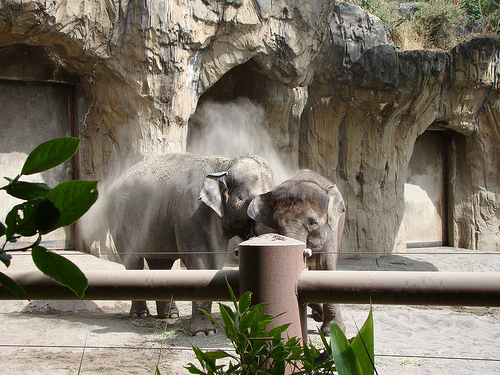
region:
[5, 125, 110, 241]
green leaves with some holes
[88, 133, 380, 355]
elephants behind a railing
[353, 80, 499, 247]
door in a stone wall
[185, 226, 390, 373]
green foliage by a post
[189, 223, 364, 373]
post and green leaves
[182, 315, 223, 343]
elephant's foot and toenails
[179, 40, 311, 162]
water flowing from mouth in wall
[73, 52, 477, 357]
elephants behind railing in a zoo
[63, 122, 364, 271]
two elephants standing together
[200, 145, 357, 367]
heads of two elephants and a post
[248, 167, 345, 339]
An elephant in an enclosure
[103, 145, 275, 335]
An elephant in an enclosure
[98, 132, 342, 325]
A pair of elephants in an enclosure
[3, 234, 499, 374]
A metal fence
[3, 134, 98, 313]
some leaves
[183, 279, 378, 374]
Some leaves in front of the fence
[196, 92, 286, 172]
A waterfall in the enclosure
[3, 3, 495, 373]
An elephant enclosure at a zoo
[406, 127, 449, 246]
Entrance to the enclosure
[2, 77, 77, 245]
Entrance to the enclosure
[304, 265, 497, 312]
Part of a metal railing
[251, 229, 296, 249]
Dirt on top of railing post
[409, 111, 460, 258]
Door in rock wall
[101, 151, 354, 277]
Two elephants of different sizes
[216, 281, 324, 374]
Green leaves on a bush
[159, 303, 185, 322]
The foot of an elephant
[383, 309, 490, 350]
Sandy floor of elephant enclosure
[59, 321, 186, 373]
Part of the wire fence enclosure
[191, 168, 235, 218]
One ear of an elephant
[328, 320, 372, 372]
Flat leaves from a landscaping plant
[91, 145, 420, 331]
a pair of elephants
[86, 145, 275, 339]
a single elephant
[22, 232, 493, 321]
part of the fence for enclosure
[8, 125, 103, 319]
some green leaves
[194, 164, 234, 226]
the larger elephants ear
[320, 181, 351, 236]
the smaller elephants ear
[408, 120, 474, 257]
one of the entrances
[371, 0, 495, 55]
Some green trees and bushes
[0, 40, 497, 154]
background of the enclousure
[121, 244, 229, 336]
the larger elephants legs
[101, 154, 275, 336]
a grey dirt covered elephant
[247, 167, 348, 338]
a grey dirt covered elephant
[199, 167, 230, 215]
a large grey elephant ear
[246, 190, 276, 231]
a large grey elephant ear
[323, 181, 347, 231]
a large grey elephant ear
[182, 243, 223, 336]
a thick grey elephant leg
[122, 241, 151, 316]
a thick grey elephant leg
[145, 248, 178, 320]
a thick grey elephant leg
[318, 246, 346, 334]
a thick grey elephant leg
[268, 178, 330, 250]
a large grey elephant head